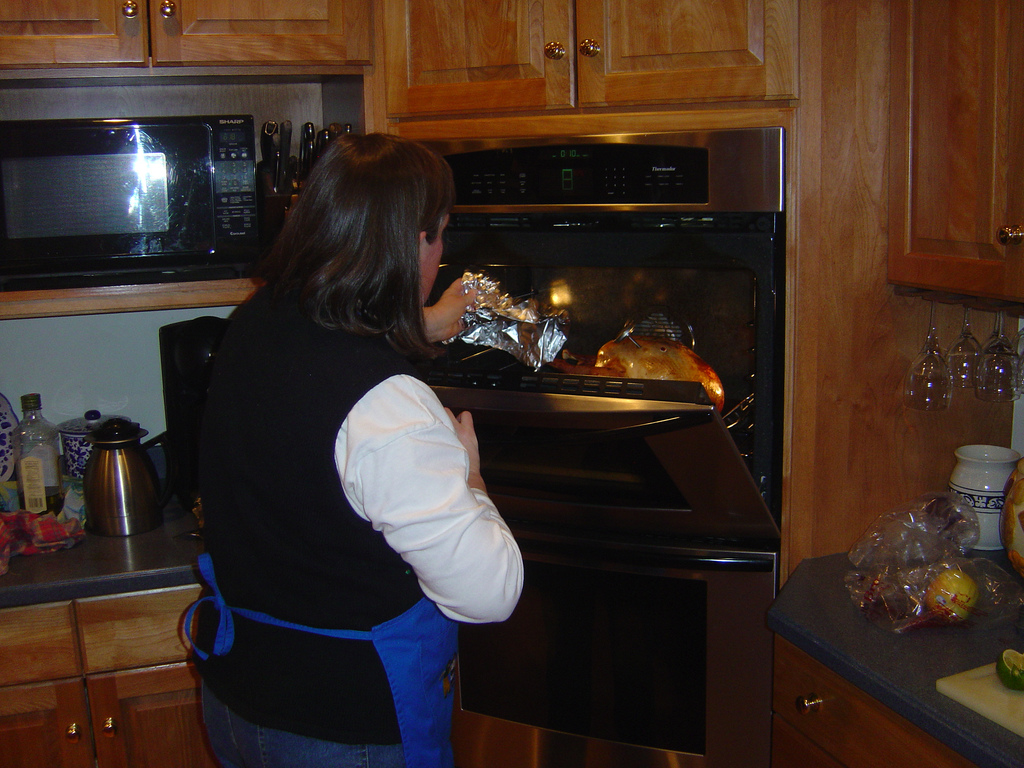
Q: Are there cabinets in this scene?
A: Yes, there is a cabinet.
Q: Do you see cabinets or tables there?
A: Yes, there is a cabinet.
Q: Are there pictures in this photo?
A: No, there are no pictures.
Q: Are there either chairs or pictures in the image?
A: No, there are no pictures or chairs.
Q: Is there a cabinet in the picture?
A: Yes, there is a cabinet.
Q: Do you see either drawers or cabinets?
A: Yes, there is a cabinet.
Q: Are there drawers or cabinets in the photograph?
A: Yes, there is a cabinet.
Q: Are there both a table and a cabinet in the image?
A: No, there is a cabinet but no tables.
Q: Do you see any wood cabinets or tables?
A: Yes, there is a wood cabinet.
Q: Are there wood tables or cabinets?
A: Yes, there is a wood cabinet.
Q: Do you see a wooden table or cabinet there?
A: Yes, there is a wood cabinet.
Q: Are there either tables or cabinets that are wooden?
A: Yes, the cabinet is wooden.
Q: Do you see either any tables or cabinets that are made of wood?
A: Yes, the cabinet is made of wood.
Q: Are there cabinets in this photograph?
A: Yes, there is a cabinet.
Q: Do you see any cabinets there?
A: Yes, there is a cabinet.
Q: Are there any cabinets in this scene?
A: Yes, there is a cabinet.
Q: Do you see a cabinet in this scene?
A: Yes, there is a cabinet.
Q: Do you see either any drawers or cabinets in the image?
A: Yes, there is a cabinet.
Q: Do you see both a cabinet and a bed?
A: No, there is a cabinet but no beds.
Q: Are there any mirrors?
A: No, there are no mirrors.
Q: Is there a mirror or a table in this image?
A: No, there are no mirrors or tables.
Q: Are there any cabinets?
A: Yes, there is a cabinet.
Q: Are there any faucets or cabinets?
A: Yes, there is a cabinet.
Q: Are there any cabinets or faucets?
A: Yes, there is a cabinet.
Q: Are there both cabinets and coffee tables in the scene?
A: No, there is a cabinet but no coffee tables.